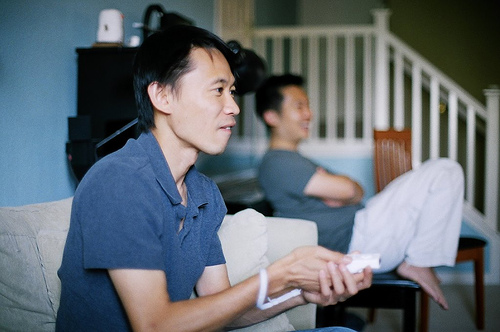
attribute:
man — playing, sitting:
[50, 20, 378, 331]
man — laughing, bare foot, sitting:
[250, 69, 468, 312]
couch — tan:
[0, 192, 324, 332]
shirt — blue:
[51, 123, 232, 331]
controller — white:
[252, 250, 387, 313]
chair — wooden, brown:
[369, 127, 492, 332]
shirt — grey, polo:
[252, 146, 368, 257]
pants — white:
[343, 155, 470, 278]